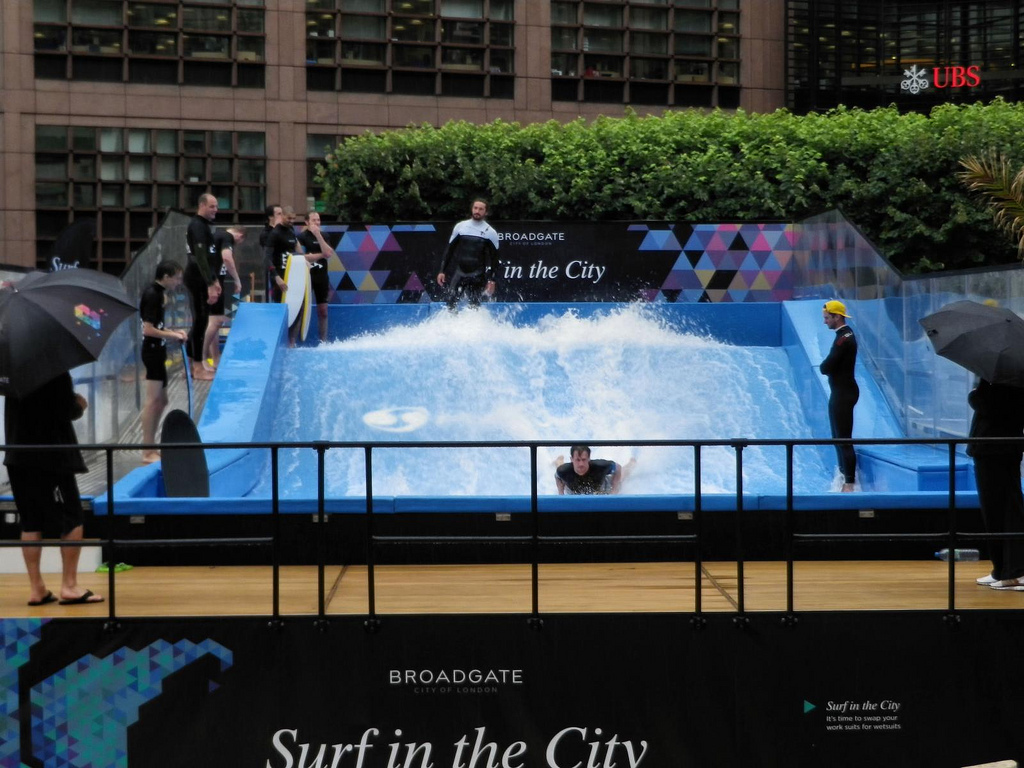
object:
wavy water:
[318, 291, 765, 354]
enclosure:
[91, 302, 980, 517]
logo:
[362, 405, 431, 433]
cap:
[822, 300, 852, 319]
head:
[822, 300, 846, 330]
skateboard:
[161, 410, 211, 497]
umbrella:
[0, 267, 142, 399]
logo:
[74, 304, 109, 341]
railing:
[0, 432, 1024, 618]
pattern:
[629, 209, 902, 304]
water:
[255, 302, 846, 492]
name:
[900, 65, 982, 96]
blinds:
[95, 125, 183, 207]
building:
[0, 0, 1024, 276]